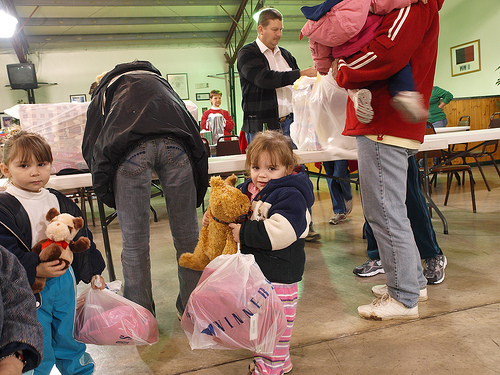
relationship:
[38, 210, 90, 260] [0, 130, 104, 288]
animal hold by girl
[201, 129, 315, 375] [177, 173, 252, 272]
baby held stuffed animal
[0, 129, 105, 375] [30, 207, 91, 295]
baby held animal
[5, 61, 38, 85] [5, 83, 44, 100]
tv on stand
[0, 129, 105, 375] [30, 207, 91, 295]
baby holding animal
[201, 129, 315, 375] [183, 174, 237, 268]
baby holding stuffed animal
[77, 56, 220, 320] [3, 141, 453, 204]
woman bending over table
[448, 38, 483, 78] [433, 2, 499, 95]
painting on wall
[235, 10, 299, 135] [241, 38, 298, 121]
man wears sweater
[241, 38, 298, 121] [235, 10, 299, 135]
sweater on man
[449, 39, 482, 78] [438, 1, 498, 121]
painting on wall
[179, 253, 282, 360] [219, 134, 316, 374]
bag held by girl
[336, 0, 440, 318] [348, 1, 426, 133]
man wearing jacket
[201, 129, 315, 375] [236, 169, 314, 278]
baby wearing coat